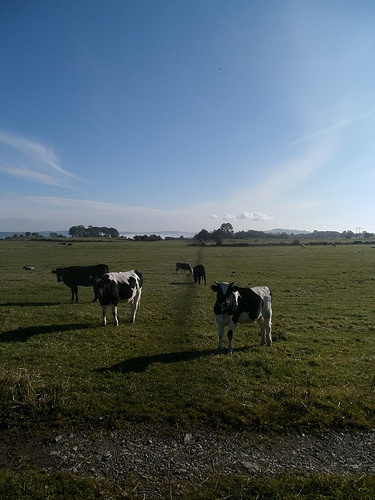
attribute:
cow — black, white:
[200, 260, 309, 342]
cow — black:
[48, 259, 98, 296]